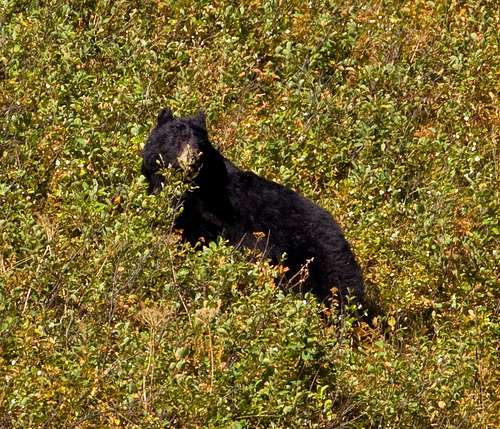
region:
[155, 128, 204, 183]
A bear foraging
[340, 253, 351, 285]
The rear of the bear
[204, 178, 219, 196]
Shadow cast on the bear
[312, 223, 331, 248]
The fur on the bear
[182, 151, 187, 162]
The bear's brownish snout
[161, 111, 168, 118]
Ear standing up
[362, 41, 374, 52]
Brown and dry leaves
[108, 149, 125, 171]
Green leaves of the plants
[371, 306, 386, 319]
Shadow cast by bear on the plants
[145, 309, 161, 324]
A dry twig sticking out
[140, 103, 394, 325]
a black bear among several trees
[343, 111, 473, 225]
green leaves of the tree branches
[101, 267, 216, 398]
several leafless branches of the trees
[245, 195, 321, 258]
black fur of the bear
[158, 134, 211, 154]
black eyes of the bear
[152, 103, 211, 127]
black furry ears of the bear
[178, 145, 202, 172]
white nose of the bear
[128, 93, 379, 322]
a bear sitting among several plants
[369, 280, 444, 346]
shadow of the bear cast on the ground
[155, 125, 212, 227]
a branch covering the face of the bear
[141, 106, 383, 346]
A black furry animal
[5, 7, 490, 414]
A busy terrain area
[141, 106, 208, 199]
Head of an animal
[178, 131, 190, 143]
Eye of an animal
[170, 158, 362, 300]
Furry body of an animal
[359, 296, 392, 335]
Furry tail of an animal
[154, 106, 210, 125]
Furry animal ears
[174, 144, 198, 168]
Brown spot on an animal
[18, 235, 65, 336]
Green leafy plant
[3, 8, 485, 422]
Green leafy brush area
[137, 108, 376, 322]
a black bear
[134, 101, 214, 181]
the head of a black bear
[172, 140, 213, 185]
the brown muzzle of a large black bear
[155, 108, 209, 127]
a black bear's ears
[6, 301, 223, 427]
an overgrowth of green and yellow plants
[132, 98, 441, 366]
a large black bear in a field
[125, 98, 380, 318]
a large black bear